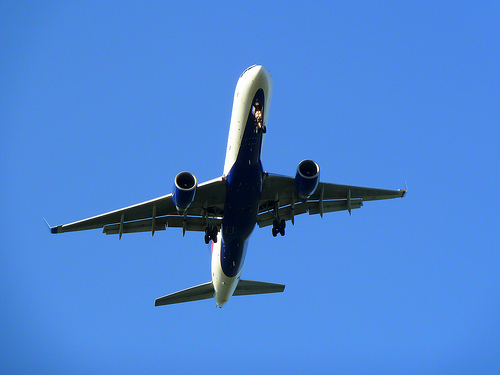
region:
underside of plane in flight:
[43, 30, 463, 351]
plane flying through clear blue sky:
[20, 10, 462, 310]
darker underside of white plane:
[50, 71, 421, 306]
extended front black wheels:
[241, 91, 276, 141]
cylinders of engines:
[145, 147, 327, 212]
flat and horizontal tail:
[135, 275, 305, 315]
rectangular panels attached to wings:
[90, 185, 380, 235]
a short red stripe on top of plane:
[200, 227, 225, 262]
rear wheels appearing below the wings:
[185, 195, 295, 250]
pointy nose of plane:
[228, 45, 285, 100]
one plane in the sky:
[51, 66, 163, 166]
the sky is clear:
[35, 52, 230, 162]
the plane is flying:
[27, 45, 334, 366]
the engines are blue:
[145, 125, 336, 211]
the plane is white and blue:
[192, 60, 325, 203]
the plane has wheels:
[215, 95, 290, 211]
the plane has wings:
[6, 155, 496, 335]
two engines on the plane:
[117, 166, 375, 221]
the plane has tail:
[135, 283, 320, 323]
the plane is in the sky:
[73, 56, 417, 345]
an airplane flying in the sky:
[47, 62, 407, 309]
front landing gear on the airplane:
[253, 112, 269, 137]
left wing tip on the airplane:
[41, 216, 67, 236]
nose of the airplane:
[248, 63, 267, 78]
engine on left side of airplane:
[174, 172, 196, 219]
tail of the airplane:
[148, 277, 286, 309]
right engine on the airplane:
[294, 157, 320, 199]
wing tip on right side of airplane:
[398, 181, 409, 195]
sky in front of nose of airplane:
[235, 20, 295, 62]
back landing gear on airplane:
[198, 215, 292, 245]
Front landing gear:
[241, 96, 271, 148]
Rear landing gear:
[188, 216, 328, 255]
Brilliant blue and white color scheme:
[123, 52, 324, 317]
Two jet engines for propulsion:
[153, 152, 338, 222]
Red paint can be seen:
[206, 228, 223, 278]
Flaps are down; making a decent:
[56, 193, 400, 246]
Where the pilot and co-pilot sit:
[223, 61, 260, 84]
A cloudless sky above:
[10, 18, 283, 210]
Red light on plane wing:
[394, 181, 420, 203]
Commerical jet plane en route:
[41, 33, 413, 338]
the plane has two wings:
[59, 83, 450, 343]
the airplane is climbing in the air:
[42, 46, 394, 331]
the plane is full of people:
[43, 59, 411, 327]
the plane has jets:
[35, 48, 413, 345]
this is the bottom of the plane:
[35, 36, 432, 313]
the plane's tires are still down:
[43, 52, 410, 313]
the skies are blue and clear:
[289, 26, 470, 158]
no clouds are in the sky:
[23, 19, 198, 193]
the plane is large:
[65, 79, 432, 334]